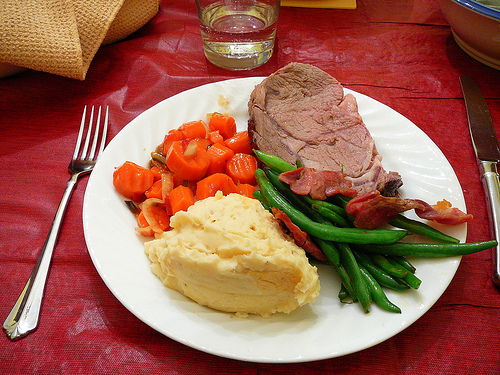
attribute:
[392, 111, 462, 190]
plate — white, round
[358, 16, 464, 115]
table — close, here, red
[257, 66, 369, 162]
meat — here, brown, done, black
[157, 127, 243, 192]
carrot — here, orange, close, cooked